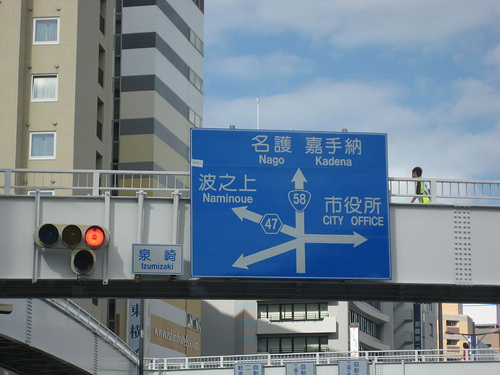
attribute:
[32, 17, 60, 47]
window — closed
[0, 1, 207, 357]
building — gray, tan, brown, white, tall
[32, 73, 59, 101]
window — closed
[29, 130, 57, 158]
window — closed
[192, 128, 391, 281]
street sign — blue, white, bilingual, directional, traffic signal, large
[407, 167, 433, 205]
man — walking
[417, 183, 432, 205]
jacket — yellow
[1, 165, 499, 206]
rail — metal, white, long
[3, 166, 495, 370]
bridge — gray, long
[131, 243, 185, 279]
street sign — blue, large, white, small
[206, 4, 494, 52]
cloud — white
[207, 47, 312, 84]
cloud — white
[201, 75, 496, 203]
cloud — white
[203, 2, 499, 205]
sky — blue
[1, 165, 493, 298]
overpass — white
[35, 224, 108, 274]
traffic light — red, gray, horizontally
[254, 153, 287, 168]
letters — asian, white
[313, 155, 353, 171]
letters — asian, white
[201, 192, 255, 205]
letters — asian, white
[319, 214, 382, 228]
letters — asian, white